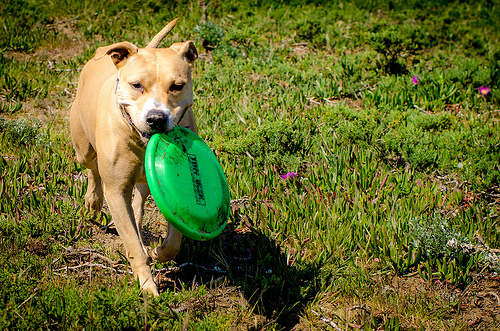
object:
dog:
[69, 28, 164, 298]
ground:
[351, 255, 466, 314]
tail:
[140, 3, 183, 45]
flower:
[478, 85, 490, 95]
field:
[2, 0, 499, 331]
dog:
[65, 17, 199, 303]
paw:
[82, 187, 106, 214]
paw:
[144, 236, 184, 262]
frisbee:
[144, 126, 233, 241]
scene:
[0, 0, 499, 331]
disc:
[142, 123, 233, 242]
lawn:
[2, 0, 498, 330]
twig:
[50, 247, 136, 280]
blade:
[314, 228, 333, 258]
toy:
[140, 123, 233, 242]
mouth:
[117, 103, 193, 153]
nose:
[144, 105, 171, 130]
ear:
[90, 39, 140, 70]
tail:
[144, 14, 182, 49]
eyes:
[127, 78, 147, 94]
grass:
[2, 0, 482, 329]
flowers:
[280, 169, 306, 181]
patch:
[19, 16, 96, 60]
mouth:
[118, 103, 193, 148]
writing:
[184, 147, 209, 206]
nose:
[141, 111, 173, 135]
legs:
[64, 114, 100, 215]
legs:
[96, 149, 161, 296]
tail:
[137, 12, 183, 44]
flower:
[411, 74, 420, 85]